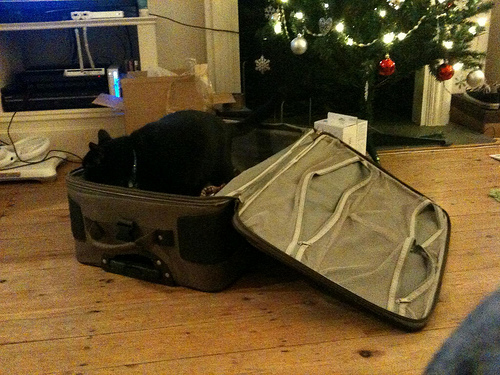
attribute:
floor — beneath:
[0, 137, 499, 373]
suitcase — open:
[63, 108, 452, 332]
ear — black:
[94, 127, 112, 144]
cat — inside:
[84, 109, 225, 183]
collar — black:
[118, 119, 144, 204]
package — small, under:
[404, 59, 454, 130]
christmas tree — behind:
[237, 5, 494, 152]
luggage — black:
[63, 116, 450, 332]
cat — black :
[131, 88, 261, 172]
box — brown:
[118, 58, 214, 135]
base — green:
[348, 63, 429, 138]